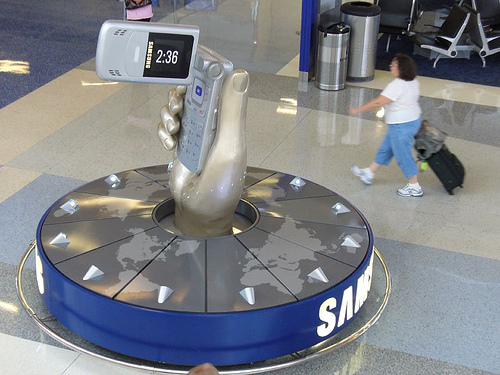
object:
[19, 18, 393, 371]
display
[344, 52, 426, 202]
lady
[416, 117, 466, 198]
backpack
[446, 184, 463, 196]
wheels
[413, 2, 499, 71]
seats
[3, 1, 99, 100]
carpet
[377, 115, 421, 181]
pants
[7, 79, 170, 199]
floor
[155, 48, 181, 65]
2:36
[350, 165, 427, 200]
sneakers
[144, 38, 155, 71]
letters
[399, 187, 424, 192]
stripes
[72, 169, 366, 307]
world map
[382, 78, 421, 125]
shirt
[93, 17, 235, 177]
phone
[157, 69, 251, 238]
hand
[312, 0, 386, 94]
trash receptical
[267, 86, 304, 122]
reflection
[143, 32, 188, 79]
clock face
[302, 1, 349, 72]
wall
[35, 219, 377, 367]
base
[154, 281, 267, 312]
cones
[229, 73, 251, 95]
fingernail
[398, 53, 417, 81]
frizzy hair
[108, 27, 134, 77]
vents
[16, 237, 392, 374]
circle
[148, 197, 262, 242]
circle